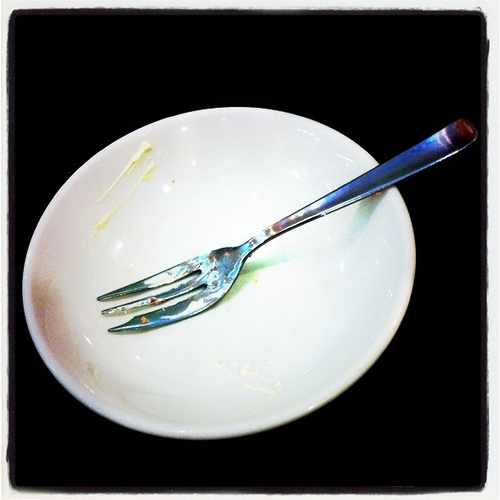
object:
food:
[149, 293, 159, 310]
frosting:
[376, 200, 401, 241]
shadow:
[232, 190, 388, 274]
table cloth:
[8, 8, 487, 491]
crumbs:
[140, 315, 148, 325]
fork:
[93, 116, 476, 334]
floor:
[107, 198, 324, 360]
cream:
[94, 141, 155, 235]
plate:
[22, 105, 419, 450]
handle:
[245, 117, 480, 252]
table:
[12, 16, 482, 483]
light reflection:
[93, 186, 318, 333]